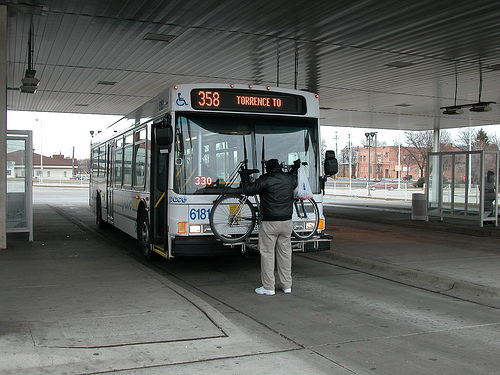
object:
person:
[236, 158, 302, 297]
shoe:
[254, 286, 276, 296]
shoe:
[281, 287, 291, 294]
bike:
[208, 157, 321, 244]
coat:
[241, 169, 298, 221]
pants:
[258, 218, 295, 290]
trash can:
[411, 192, 428, 221]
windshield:
[172, 110, 322, 195]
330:
[194, 176, 214, 186]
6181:
[189, 208, 211, 221]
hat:
[264, 158, 282, 173]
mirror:
[324, 150, 339, 176]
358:
[197, 90, 220, 107]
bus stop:
[0, 0, 499, 374]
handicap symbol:
[175, 92, 189, 107]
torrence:
[236, 96, 271, 107]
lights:
[177, 221, 186, 234]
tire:
[136, 207, 156, 262]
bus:
[87, 81, 333, 262]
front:
[167, 81, 335, 259]